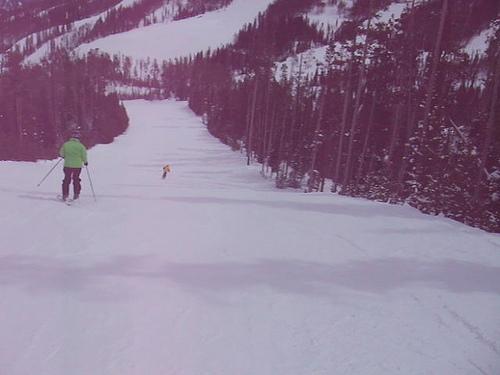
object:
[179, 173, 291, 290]
snow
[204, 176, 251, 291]
ground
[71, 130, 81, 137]
hat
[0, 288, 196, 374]
snow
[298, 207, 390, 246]
ground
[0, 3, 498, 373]
mountain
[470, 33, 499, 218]
line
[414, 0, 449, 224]
tree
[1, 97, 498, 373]
slope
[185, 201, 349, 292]
snow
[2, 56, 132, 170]
green trees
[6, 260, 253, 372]
ground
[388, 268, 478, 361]
snow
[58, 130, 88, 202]
male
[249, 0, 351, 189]
trees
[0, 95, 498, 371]
snow path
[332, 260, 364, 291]
snow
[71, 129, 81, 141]
head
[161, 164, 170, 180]
person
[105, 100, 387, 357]
slopes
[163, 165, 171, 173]
yellow jacket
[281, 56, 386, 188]
long neck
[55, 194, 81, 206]
ski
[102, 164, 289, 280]
slope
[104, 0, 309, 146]
mountain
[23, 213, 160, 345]
snow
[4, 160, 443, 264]
ground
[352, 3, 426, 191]
tree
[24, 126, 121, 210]
skiing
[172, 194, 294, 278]
ground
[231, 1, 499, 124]
hill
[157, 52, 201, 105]
trees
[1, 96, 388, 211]
downhill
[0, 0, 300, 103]
mountain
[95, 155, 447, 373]
slope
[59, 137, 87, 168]
jacket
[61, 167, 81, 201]
pants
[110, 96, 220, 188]
slope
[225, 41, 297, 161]
trees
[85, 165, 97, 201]
stick